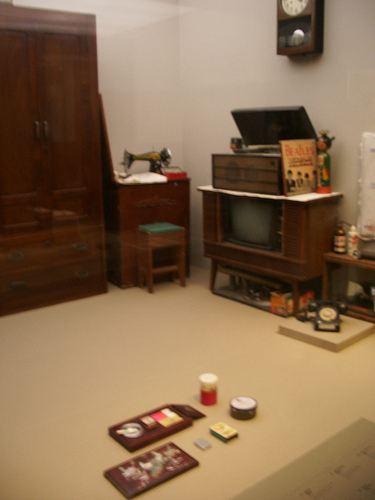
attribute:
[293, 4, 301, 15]
number — black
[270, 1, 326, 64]
clock —  brown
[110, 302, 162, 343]
floor — tan colored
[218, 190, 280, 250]
television — old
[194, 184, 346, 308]
television — old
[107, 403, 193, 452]
tray — wooden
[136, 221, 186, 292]
stool — wooden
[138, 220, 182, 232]
cushion — green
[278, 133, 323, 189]
record — beatles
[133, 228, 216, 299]
stool — wooden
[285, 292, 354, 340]
phone — dial up, black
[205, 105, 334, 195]
record player — vintage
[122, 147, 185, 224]
sewing machine — black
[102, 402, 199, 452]
tray — wooden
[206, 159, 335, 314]
furniture — old, fashioned, tv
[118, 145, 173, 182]
sewing machine — black, gold